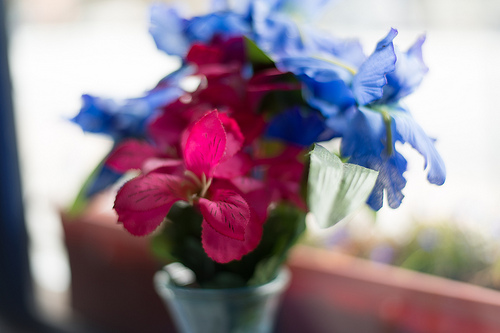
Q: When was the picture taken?
A: Daytime.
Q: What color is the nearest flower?
A: Pink.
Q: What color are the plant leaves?
A: Green.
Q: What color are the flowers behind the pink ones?
A: Blue.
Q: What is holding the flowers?
A: A vase.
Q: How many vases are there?
A: One.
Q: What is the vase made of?
A: Glass.